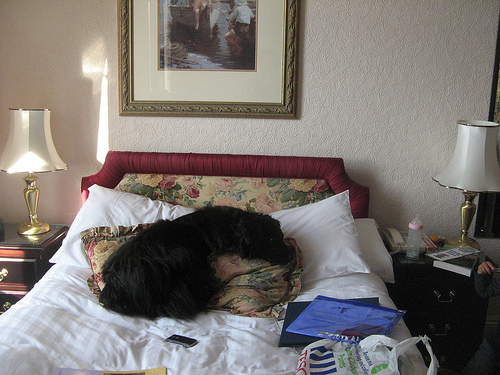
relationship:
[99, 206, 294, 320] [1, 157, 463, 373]
dog in bed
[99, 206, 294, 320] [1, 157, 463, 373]
dog sleeping in bed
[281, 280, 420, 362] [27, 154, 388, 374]
shirt placed in bed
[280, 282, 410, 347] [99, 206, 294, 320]
shirt placed before dog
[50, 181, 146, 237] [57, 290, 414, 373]
pillow in bed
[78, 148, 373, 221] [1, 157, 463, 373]
floral headboard on bed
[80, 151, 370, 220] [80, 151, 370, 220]
floral headboard on floral headboard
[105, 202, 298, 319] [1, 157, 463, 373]
dog on bed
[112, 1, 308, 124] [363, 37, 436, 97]
picture on table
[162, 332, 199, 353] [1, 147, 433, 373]
cellphone on bed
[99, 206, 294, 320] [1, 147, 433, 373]
dog on bed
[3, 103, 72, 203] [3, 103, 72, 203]
sunlight on sunlight